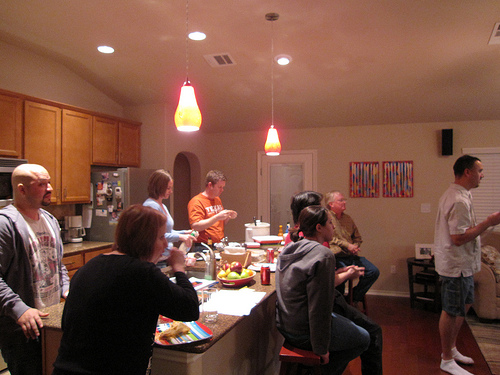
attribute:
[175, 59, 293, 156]
lamps — yellow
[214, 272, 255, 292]
bowl — red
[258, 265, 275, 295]
can — red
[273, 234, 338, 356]
jacket — gray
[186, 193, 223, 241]
tshirt — orange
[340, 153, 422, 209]
paintings — colorful